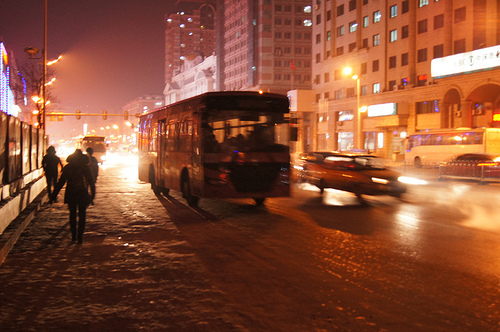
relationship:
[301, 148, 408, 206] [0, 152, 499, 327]
car heading down road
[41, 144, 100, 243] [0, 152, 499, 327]
people walking down street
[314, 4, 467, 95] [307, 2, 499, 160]
windows are on building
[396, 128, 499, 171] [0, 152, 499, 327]
bus going down road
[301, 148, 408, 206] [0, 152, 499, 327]
car going down road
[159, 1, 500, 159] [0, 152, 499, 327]
buildings are on side of road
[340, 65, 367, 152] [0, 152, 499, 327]
streetlight on side of road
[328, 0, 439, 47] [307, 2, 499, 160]
lights on inside of building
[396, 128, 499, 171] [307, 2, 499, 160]
bus stopped in front of building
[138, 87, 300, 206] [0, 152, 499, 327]
bus travelling down street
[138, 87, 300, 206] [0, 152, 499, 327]
bus driving on street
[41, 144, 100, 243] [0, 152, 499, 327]
people are walking on street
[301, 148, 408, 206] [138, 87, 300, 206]
vehicle driving past bus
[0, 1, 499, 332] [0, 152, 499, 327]
scene takes place on street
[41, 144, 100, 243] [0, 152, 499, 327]
people are walking along road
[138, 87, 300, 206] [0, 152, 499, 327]
bus travelling on street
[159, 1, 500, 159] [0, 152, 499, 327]
buildings are beside street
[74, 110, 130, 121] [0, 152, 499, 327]
traffic lights are above street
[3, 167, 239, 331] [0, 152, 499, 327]
snow on ground